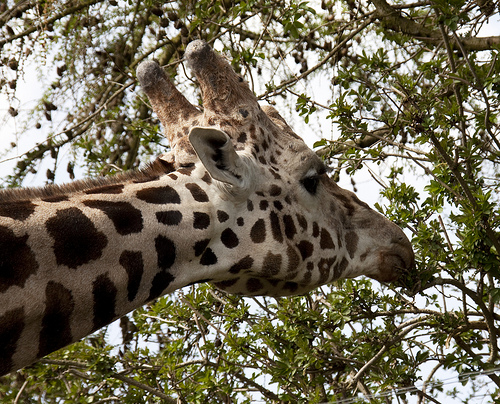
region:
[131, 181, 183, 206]
brown spot on a giraffe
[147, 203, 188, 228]
brown spot on a giraffe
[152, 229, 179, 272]
brown spot on a giraffe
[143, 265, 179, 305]
brown spot on a giraffe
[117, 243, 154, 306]
brown spot on a giraffe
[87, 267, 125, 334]
brown spot on a giraffe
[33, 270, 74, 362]
brown spot on a giraffe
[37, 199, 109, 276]
brown spot on a giraffe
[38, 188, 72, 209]
brown spot on a giraffe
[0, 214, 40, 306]
brown spot on a giraffe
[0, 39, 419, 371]
Giraffe eating green foliage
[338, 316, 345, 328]
Small leaf is green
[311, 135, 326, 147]
Small green leaf attached to brown tree branch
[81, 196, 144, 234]
Brown spot on giraffe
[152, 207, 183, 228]
Brown spot on giraffe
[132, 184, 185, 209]
Brown spot on giraffe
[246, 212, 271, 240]
Brown spot on giraffe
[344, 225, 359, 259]
Brown spot on giraffe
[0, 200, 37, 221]
Brown spot near mane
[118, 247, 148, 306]
Brown spot on giraffe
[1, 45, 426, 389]
white giraffe with dark brown spots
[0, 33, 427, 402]
view of giraffe from neck up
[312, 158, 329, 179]
black spot above eye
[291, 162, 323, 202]
black eye surrounded by white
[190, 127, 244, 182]
white ear with black inside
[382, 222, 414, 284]
brown tip of nose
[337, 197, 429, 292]
giraffe eating tree leaves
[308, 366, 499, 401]
thin wires in lower right corner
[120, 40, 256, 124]
light brown horns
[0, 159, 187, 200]
thin brown hair on giraffe neck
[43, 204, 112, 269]
Brown spot on giraffe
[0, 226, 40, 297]
Brown spot on giraffe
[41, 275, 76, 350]
Brown spot on giraffe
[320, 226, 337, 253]
Brown spot on giraffe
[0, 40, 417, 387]
Giraffe eating leaf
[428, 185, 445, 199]
Leaf is green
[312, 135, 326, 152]
Green leaf attached to brown branch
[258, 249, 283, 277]
Brown spot on giraffe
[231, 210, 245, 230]
brown spot on a giraffe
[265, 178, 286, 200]
brown spot on a giraffe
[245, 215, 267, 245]
brown spot on a giraffe